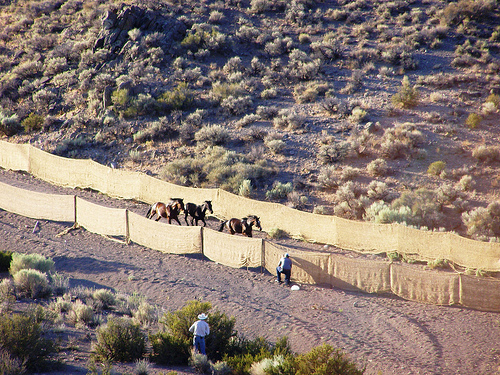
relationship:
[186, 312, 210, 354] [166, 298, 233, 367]
man behind bush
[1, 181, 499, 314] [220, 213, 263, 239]
border next to horse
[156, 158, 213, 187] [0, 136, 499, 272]
bush next to border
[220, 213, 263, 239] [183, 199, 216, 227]
horse in front of horse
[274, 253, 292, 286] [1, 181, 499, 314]
man kneeling close to border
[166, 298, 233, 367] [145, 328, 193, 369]
bush near bush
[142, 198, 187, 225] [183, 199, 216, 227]
horse behind horse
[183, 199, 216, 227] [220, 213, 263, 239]
horse behind horse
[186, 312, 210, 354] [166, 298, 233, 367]
man hiding behind bush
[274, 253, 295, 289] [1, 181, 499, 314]
man hiding behind border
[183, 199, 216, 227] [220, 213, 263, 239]
horse following horse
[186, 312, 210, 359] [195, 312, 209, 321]
man wearing hat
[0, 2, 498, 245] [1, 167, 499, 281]
trees behind road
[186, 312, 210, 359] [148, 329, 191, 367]
man trimming bush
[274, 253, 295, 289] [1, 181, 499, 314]
man making border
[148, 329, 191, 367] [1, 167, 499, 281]
bush near road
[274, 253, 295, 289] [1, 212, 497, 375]
man kneeling on dirt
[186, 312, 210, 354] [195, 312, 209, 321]
man wearing hat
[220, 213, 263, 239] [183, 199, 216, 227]
horse running with horse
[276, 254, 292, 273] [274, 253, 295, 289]
t-shirt on man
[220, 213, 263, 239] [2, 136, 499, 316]
horse inside enclosure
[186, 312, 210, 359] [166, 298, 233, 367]
man standing behind bush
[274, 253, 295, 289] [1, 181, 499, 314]
man working on border